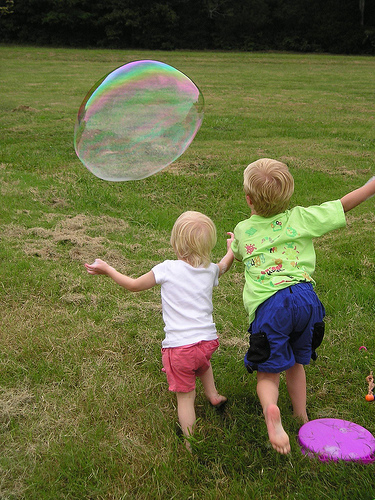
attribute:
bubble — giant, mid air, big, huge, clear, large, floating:
[69, 61, 205, 183]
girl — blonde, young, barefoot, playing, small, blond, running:
[89, 214, 238, 456]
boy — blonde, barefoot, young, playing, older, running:
[231, 159, 374, 457]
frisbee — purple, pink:
[300, 415, 374, 460]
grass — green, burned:
[3, 45, 374, 498]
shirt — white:
[155, 258, 224, 353]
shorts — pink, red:
[166, 341, 222, 395]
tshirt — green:
[231, 200, 347, 323]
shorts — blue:
[239, 280, 330, 378]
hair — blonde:
[166, 209, 218, 270]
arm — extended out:
[216, 245, 238, 279]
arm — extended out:
[108, 262, 163, 295]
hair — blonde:
[242, 155, 296, 217]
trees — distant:
[1, 1, 373, 64]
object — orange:
[362, 367, 374, 401]